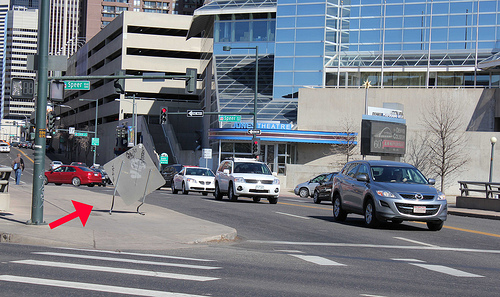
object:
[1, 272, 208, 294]
stripes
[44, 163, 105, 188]
car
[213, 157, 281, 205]
car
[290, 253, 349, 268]
paint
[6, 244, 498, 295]
asphalt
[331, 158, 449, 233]
car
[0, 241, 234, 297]
crosswalk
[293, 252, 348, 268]
line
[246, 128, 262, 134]
sign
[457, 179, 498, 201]
median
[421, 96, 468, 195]
tree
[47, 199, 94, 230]
arrow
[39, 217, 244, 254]
corner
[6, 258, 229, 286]
line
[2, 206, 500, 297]
intersection